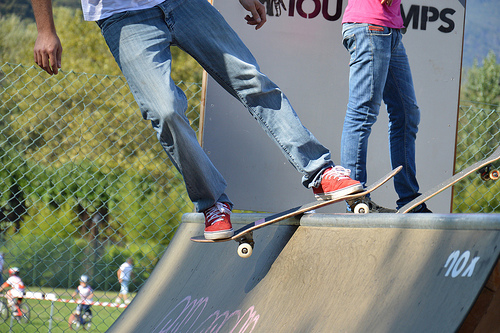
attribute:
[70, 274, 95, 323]
child — small, little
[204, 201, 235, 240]
shoe — red, white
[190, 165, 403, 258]
skateboard — black, white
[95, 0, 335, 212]
jeans — denim, blue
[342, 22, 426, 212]
jeans — denim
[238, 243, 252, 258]
wheel — white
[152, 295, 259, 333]
writing — pink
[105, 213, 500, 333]
ramp — black, large, here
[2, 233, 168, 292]
fence — large, here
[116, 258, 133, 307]
man — here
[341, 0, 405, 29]
shirt — pink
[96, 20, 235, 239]
leg — here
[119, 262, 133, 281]
shirt — white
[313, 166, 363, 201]
shoe — red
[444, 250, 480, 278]
writing — white